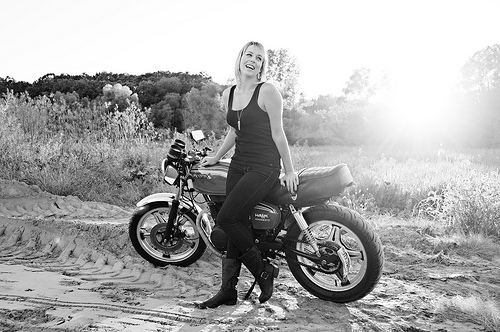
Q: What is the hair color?
A: Blonde.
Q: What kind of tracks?
A: Tire.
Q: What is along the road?
A: Bushes.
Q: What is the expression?
A: Smiling.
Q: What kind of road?
A: Dirt.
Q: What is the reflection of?
A: Sunlgiht.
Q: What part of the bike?
A: Wheel.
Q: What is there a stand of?
A: Trees.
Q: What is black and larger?
A: Tire.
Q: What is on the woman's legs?
A: Pants.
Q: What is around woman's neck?
A: Necklace.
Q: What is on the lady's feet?
A: Boots.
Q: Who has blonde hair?
A: Lady near bike.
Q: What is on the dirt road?
A: Motorcycle.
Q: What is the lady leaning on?
A: Bike.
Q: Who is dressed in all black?
A: Blonde woman.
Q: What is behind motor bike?
A: Trees.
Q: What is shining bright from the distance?
A: Sun shine.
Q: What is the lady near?
A: A motorcycle.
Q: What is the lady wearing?
A: Black pants.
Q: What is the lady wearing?
A: Black tank top.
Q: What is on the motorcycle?
A: A tire.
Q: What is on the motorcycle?
A: A tire.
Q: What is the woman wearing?
A: Black pants.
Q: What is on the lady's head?
A: Blonde hair.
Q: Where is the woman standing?
A: In front of the motorcycle.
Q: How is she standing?
A: Slightly leaning.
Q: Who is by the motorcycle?
A: A woman.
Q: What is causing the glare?
A: The sun.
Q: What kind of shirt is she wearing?
A: Tank top.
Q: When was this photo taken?
A: During the day.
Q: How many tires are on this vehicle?
A: Two.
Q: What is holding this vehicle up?
A: Kickstand.